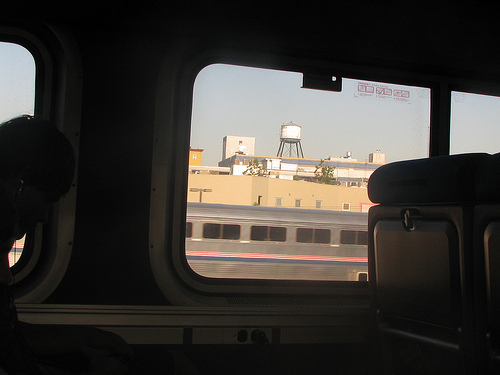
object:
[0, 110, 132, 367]
passenger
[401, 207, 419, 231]
latch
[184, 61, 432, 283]
window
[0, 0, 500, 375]
train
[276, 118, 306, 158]
water tower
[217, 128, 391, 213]
building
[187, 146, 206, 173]
building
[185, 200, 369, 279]
train car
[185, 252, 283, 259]
stripe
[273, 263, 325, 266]
stripe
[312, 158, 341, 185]
bush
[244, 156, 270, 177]
bush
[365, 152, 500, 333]
seat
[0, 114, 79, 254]
head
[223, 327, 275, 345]
outlet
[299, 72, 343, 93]
latch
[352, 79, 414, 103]
instructions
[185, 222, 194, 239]
window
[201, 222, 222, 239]
window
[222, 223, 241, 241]
window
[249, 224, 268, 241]
window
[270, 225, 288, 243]
window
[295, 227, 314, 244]
window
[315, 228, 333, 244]
window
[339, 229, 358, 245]
window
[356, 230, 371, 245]
window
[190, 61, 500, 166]
sky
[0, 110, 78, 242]
hair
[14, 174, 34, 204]
headphones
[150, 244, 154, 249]
screws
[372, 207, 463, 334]
tray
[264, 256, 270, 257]
stripes